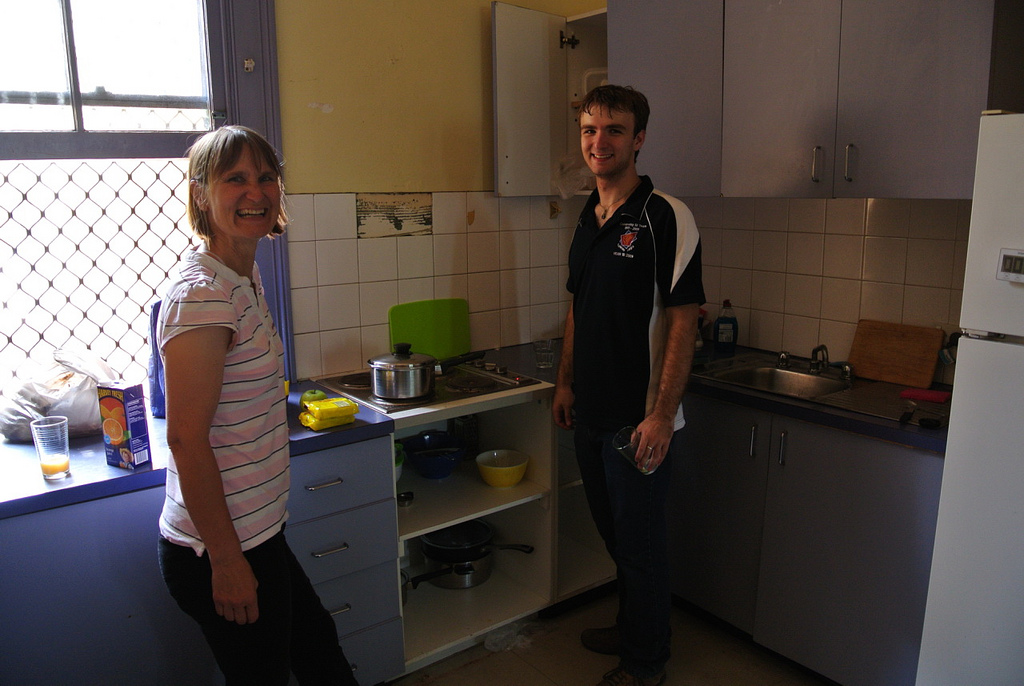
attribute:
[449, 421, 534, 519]
mixing bowl — yellow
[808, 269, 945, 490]
cutting board — wooden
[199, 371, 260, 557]
shirt — stiped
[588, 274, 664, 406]
shirt — black and white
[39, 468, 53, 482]
juice — orange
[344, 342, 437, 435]
pot — steel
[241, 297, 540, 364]
board — green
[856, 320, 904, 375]
board — wooden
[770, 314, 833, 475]
faucet — silver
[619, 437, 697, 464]
glass — clear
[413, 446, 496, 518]
pot — metal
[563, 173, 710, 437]
shirt — black, white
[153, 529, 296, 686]
pants — black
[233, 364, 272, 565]
shirt — short sleeved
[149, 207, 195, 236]
hair — short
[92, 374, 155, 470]
box — purple, small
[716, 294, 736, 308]
cap — red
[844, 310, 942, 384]
cutter board — wooden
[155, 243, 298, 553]
shirt — pink, white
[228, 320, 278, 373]
lines — black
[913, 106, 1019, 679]
refrigerator — white, clean